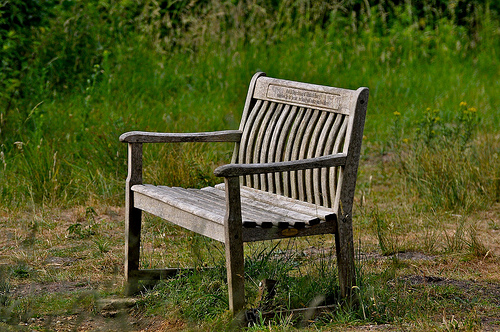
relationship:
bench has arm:
[101, 68, 377, 307] [208, 157, 362, 197]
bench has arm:
[101, 68, 377, 307] [123, 104, 243, 163]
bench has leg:
[101, 68, 377, 307] [98, 211, 191, 282]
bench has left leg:
[101, 68, 377, 307] [218, 238, 357, 309]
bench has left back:
[101, 68, 377, 307] [299, 95, 346, 207]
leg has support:
[98, 211, 191, 282] [131, 179, 273, 219]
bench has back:
[101, 68, 377, 307] [244, 71, 365, 146]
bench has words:
[101, 68, 377, 307] [273, 85, 340, 107]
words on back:
[273, 85, 340, 107] [244, 71, 365, 146]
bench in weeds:
[101, 68, 377, 307] [161, 272, 494, 329]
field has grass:
[40, 31, 235, 128] [400, 70, 498, 211]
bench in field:
[101, 68, 377, 307] [40, 31, 235, 128]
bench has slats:
[101, 68, 377, 307] [258, 108, 265, 170]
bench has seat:
[101, 68, 377, 307] [157, 174, 323, 232]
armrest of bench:
[123, 104, 243, 163] [101, 68, 377, 307]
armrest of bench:
[208, 157, 362, 197] [101, 68, 377, 307]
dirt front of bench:
[66, 293, 204, 332] [101, 68, 377, 307]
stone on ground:
[105, 291, 138, 309] [21, 243, 185, 321]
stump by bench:
[261, 285, 327, 319] [101, 68, 377, 307]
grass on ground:
[400, 70, 498, 211] [21, 243, 185, 321]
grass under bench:
[171, 257, 332, 307] [101, 68, 377, 307]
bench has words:
[101, 68, 377, 307] [276, 86, 334, 101]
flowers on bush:
[390, 102, 495, 140] [401, 98, 497, 162]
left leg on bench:
[218, 238, 357, 309] [101, 68, 377, 307]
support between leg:
[131, 179, 273, 219] [98, 211, 191, 282]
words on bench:
[273, 85, 340, 107] [101, 68, 377, 307]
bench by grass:
[101, 68, 377, 307] [120, 10, 487, 99]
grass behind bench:
[120, 10, 487, 99] [101, 68, 377, 307]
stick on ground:
[259, 297, 330, 313] [21, 243, 185, 321]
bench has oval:
[101, 68, 377, 307] [281, 227, 302, 238]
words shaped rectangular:
[273, 85, 340, 107] [261, 81, 360, 112]